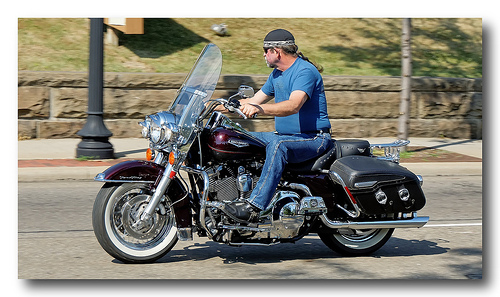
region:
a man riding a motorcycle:
[71, 27, 438, 268]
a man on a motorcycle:
[220, 25, 340, 220]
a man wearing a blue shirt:
[235, 28, 334, 141]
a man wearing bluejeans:
[228, 29, 338, 211]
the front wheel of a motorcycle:
[84, 162, 186, 263]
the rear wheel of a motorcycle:
[316, 190, 403, 256]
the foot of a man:
[213, 196, 267, 224]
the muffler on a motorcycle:
[313, 212, 438, 234]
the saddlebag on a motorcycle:
[321, 148, 433, 216]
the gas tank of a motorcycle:
[196, 120, 267, 170]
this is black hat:
[258, 27, 302, 49]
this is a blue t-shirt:
[260, 56, 332, 136]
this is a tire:
[90, 159, 188, 264]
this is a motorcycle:
[88, 40, 432, 265]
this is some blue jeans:
[239, 128, 334, 212]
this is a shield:
[165, 39, 226, 129]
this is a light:
[135, 105, 197, 145]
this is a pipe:
[315, 210, 433, 232]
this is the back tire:
[312, 179, 397, 256]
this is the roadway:
[0, 177, 498, 282]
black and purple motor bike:
[91, 44, 427, 256]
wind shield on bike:
[173, 42, 222, 117]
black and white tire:
[93, 184, 178, 262]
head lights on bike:
[140, 112, 175, 142]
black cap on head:
[261, 27, 291, 44]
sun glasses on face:
[261, 45, 266, 50]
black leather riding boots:
[221, 200, 257, 220]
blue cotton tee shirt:
[261, 61, 329, 138]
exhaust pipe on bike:
[323, 213, 429, 230]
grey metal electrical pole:
[76, 19, 114, 156]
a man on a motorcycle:
[94, 27, 433, 262]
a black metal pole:
[82, 17, 114, 164]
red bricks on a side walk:
[24, 157, 101, 166]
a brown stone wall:
[25, 73, 142, 138]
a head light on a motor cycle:
[147, 110, 171, 143]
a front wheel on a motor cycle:
[91, 168, 191, 260]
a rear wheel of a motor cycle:
[329, 217, 396, 256]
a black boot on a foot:
[222, 198, 258, 225]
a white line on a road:
[422, 217, 483, 230]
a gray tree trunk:
[394, 17, 415, 139]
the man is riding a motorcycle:
[99, 27, 456, 278]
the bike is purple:
[36, 95, 267, 209]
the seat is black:
[290, 134, 350, 171]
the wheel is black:
[67, 181, 179, 262]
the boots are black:
[206, 183, 278, 245]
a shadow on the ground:
[172, 225, 437, 270]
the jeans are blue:
[212, 107, 330, 202]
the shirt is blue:
[243, 57, 335, 131]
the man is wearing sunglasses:
[235, 21, 284, 66]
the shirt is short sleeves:
[227, 56, 338, 133]